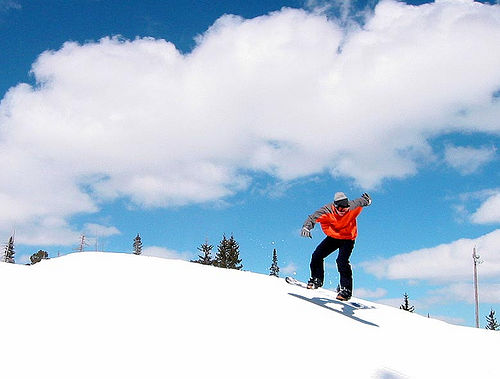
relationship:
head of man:
[331, 190, 349, 213] [300, 189, 371, 301]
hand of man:
[300, 228, 313, 240] [300, 189, 371, 301]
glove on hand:
[299, 226, 314, 240] [300, 228, 313, 240]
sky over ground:
[1, 1, 499, 328] [0, 252, 499, 376]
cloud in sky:
[2, 0, 499, 246] [1, 1, 499, 328]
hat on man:
[333, 189, 346, 200] [300, 189, 371, 301]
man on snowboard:
[300, 189, 371, 301] [285, 275, 369, 311]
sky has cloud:
[1, 1, 499, 328] [2, 0, 499, 246]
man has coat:
[300, 189, 371, 301] [303, 196, 368, 241]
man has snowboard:
[300, 189, 371, 301] [285, 275, 369, 311]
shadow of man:
[310, 294, 375, 316] [300, 189, 371, 301]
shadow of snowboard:
[289, 291, 378, 327] [285, 275, 369, 311]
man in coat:
[300, 189, 371, 301] [303, 196, 368, 241]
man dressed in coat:
[300, 189, 371, 301] [303, 196, 368, 241]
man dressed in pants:
[300, 189, 371, 301] [309, 235, 354, 292]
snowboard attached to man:
[285, 275, 369, 311] [300, 189, 371, 301]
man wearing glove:
[300, 189, 371, 301] [299, 226, 314, 240]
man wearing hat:
[300, 189, 371, 301] [333, 189, 346, 200]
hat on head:
[333, 189, 346, 200] [331, 190, 349, 213]